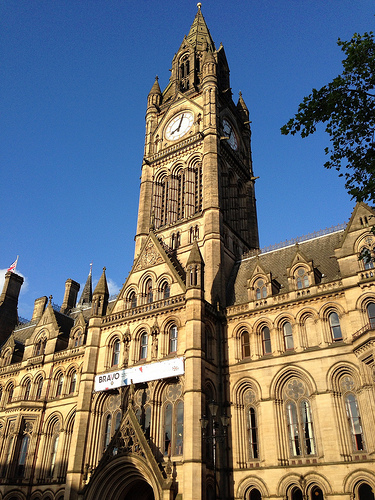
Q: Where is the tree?
A: Beside the building.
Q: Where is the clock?
A: On the steeple?.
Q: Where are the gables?
A: On the roof.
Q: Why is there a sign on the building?
A: To advertise an event.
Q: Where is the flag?
A: Atop the tower on the left.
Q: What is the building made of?
A: Stone.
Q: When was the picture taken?
A: On a clear day.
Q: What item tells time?
A: A clock.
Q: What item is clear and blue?
A: The sky.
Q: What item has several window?
A: A building.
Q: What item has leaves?
A: A tree.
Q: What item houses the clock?
A: The tower.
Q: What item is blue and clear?
A: The sky.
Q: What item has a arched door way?
A: A building.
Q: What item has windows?
A: A building.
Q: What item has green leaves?
A: The tree.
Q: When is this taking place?
A: Daytime.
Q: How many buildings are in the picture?
A: One.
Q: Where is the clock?
A: On the top of the tower on the building.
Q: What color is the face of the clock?
A: White and black.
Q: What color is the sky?
A: Blue.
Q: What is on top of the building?
A: Steeple.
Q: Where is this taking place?
A: In the city.